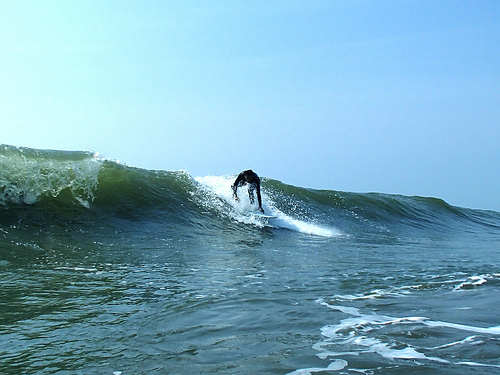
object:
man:
[230, 169, 266, 214]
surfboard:
[247, 206, 276, 219]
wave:
[1, 142, 500, 239]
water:
[0, 142, 499, 375]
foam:
[320, 306, 381, 330]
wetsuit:
[232, 170, 264, 206]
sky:
[0, 0, 499, 214]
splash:
[199, 174, 349, 239]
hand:
[257, 206, 265, 215]